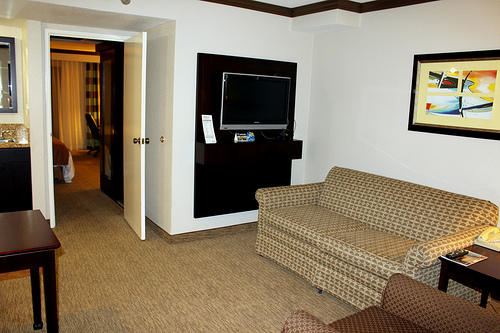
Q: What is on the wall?
A: A painting.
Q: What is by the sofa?
A: An end table.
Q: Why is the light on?
A: To see.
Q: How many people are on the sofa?
A: Zero.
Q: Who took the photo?
A: You did.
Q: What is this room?
A: A living room.